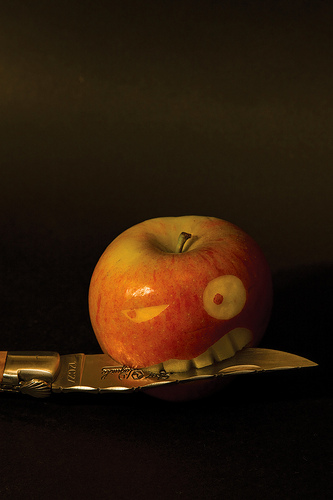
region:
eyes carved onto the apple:
[122, 275, 246, 323]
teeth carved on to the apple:
[143, 325, 249, 372]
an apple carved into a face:
[83, 212, 260, 368]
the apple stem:
[172, 229, 187, 248]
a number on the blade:
[64, 358, 72, 381]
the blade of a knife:
[48, 346, 314, 386]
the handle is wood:
[0, 348, 3, 381]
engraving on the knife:
[98, 366, 171, 382]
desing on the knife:
[11, 380, 50, 396]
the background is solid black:
[1, 3, 327, 498]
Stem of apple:
[166, 229, 196, 256]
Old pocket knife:
[0, 349, 325, 392]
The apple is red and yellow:
[86, 215, 269, 378]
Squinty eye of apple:
[117, 301, 171, 325]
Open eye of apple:
[200, 273, 248, 321]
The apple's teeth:
[140, 325, 254, 375]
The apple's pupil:
[212, 292, 223, 306]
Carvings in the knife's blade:
[98, 363, 143, 382]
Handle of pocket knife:
[0, 349, 9, 384]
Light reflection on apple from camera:
[123, 283, 161, 302]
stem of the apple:
[168, 229, 194, 252]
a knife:
[261, 352, 314, 371]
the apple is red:
[104, 258, 142, 284]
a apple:
[80, 223, 288, 376]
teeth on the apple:
[192, 352, 216, 371]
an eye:
[201, 282, 255, 322]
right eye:
[115, 303, 174, 321]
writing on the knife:
[101, 353, 118, 381]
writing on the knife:
[67, 353, 79, 384]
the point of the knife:
[305, 356, 318, 368]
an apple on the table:
[36, 189, 262, 436]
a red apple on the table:
[59, 209, 282, 484]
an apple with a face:
[40, 225, 285, 495]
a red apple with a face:
[48, 198, 278, 497]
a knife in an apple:
[32, 219, 324, 499]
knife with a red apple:
[65, 232, 280, 490]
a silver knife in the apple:
[87, 257, 296, 473]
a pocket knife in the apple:
[42, 288, 318, 430]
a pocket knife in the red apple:
[81, 226, 316, 431]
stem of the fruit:
[159, 214, 203, 257]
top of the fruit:
[109, 211, 244, 282]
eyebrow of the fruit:
[108, 265, 164, 309]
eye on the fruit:
[185, 274, 249, 323]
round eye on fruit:
[199, 283, 234, 316]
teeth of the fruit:
[150, 329, 257, 379]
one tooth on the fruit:
[210, 323, 243, 368]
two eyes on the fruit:
[107, 264, 253, 339]